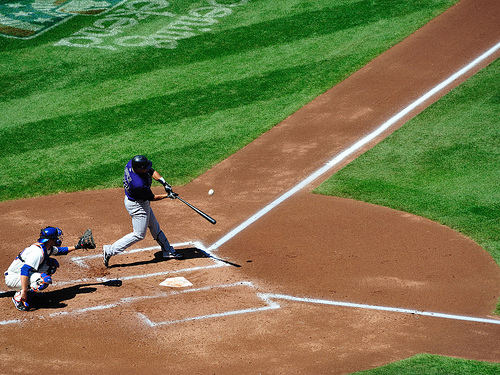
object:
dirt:
[0, 0, 499, 372]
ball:
[207, 187, 215, 196]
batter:
[102, 153, 184, 269]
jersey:
[123, 159, 154, 201]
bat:
[160, 184, 216, 227]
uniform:
[4, 240, 69, 301]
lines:
[2, 47, 500, 329]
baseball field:
[3, 0, 498, 370]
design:
[0, 0, 244, 52]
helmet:
[129, 153, 157, 172]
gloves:
[157, 176, 173, 193]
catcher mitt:
[77, 228, 96, 249]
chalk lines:
[71, 242, 280, 328]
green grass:
[149, 88, 467, 188]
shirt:
[9, 242, 68, 276]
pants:
[9, 257, 59, 297]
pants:
[110, 197, 175, 259]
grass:
[83, 55, 172, 128]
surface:
[151, 276, 204, 297]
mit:
[72, 224, 102, 256]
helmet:
[38, 226, 63, 243]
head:
[36, 223, 65, 249]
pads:
[35, 275, 49, 290]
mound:
[6, 196, 448, 373]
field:
[2, 0, 484, 370]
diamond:
[158, 275, 195, 288]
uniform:
[107, 161, 175, 251]